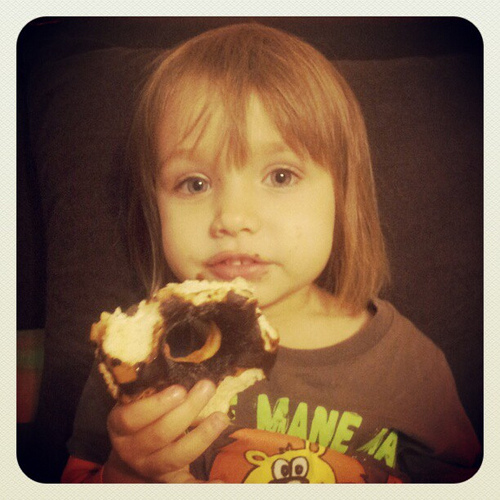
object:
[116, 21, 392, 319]
hair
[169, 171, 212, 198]
eyes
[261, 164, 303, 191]
eyes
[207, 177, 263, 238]
nose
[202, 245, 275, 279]
mouth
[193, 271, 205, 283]
crumbs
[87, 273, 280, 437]
donut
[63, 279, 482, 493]
pullover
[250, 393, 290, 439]
m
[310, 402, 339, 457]
n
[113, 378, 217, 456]
fingers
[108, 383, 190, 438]
fingers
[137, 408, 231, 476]
fingers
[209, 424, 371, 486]
lion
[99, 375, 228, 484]
hand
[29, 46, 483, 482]
chair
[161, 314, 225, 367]
center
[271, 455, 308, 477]
eyes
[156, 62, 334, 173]
bangs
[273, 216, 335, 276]
cheeks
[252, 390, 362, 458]
mane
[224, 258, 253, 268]
teeth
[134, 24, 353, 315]
head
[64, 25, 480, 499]
girl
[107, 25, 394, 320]
brown hair